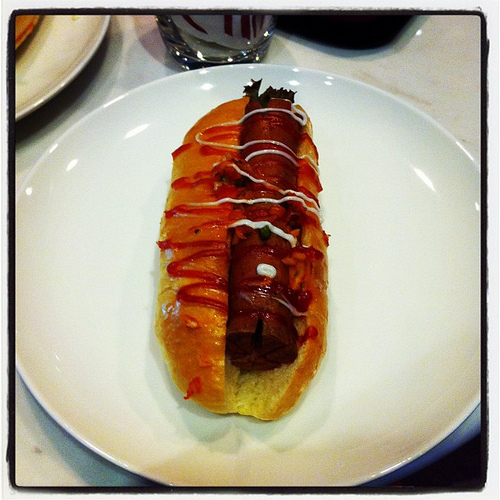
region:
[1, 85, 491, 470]
A hot dog on a plate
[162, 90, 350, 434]
A hot dog with ketchup and white dressing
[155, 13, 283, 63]
The bottom of a clear glass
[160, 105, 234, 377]
The outside of the bun is glazed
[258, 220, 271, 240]
A green speck on the hot dog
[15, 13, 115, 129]
A portion of a plate with food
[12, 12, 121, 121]
The shadow is underneath the plate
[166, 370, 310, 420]
The bun is yellow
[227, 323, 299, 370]
The hot dog has cuts in it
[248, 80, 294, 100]
A green portion of lettuce sticks out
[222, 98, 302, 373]
hot dog in bun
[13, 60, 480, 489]
large white plate on table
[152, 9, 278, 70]
clear glass near white plate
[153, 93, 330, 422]
brown bun with hot dog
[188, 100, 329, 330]
white sauce drizzled on hot dog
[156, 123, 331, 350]
red sauce drizzled on hot dog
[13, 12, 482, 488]
white table under plate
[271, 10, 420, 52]
dark shadow near water glass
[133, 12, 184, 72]
shadow from water glass on table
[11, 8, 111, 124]
portion of white plate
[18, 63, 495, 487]
A hot dog on a white plate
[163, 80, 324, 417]
A hot dog in a bun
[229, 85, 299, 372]
A hot dog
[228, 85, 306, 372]
A grilled hot dog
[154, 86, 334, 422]
A grilled hot do in a bun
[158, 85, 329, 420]
A grilled hut dog with mayonnaise and ketchup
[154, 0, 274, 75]
A glass of water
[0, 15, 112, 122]
A small plate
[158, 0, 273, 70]
A glass of water on the table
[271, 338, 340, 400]
part of a plate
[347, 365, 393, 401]
part of a plate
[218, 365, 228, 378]
edge of a bread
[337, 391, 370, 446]
part of a plate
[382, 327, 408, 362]
part of a plate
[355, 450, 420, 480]
edge of a plate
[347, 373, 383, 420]
part of a plate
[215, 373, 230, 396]
edge of a bread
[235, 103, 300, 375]
sausage on the bun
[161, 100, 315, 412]
bread with sausage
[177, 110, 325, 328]
red and white toppings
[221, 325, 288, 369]
edge of sausage is split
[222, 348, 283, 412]
inner part of bun is yellow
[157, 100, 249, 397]
outer part of bun is gold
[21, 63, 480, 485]
white plate on table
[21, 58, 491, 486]
white plate with food on it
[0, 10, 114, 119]
edge of a white plate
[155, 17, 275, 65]
bottom of cup by plate